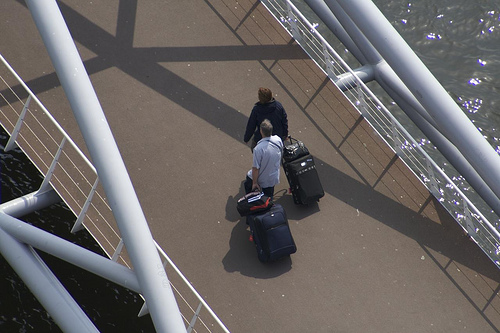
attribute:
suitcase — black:
[283, 154, 327, 210]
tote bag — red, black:
[235, 190, 270, 212]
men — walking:
[223, 78, 291, 201]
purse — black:
[287, 141, 307, 153]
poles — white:
[3, 200, 127, 332]